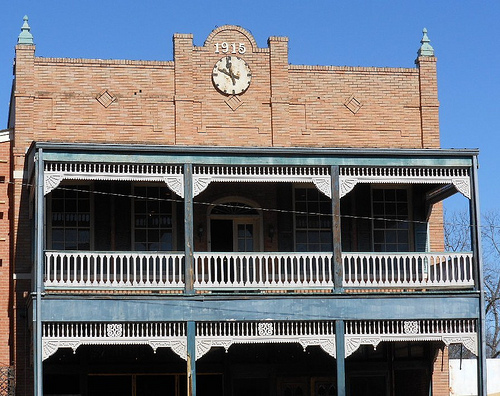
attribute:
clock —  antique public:
[206, 49, 257, 94]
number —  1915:
[214, 36, 260, 56]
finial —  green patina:
[16, 136, 483, 384]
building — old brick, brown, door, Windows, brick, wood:
[11, 14, 484, 389]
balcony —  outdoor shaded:
[15, 132, 481, 393]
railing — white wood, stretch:
[25, 135, 467, 386]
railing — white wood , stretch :
[12, 121, 481, 376]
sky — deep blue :
[71, 11, 445, 33]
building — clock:
[211, 51, 254, 99]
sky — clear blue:
[321, 14, 440, 41]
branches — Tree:
[438, 219, 483, 249]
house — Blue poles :
[24, 154, 484, 393]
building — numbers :
[194, 40, 256, 53]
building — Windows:
[5, 21, 443, 131]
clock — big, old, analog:
[211, 54, 250, 94]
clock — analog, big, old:
[209, 57, 254, 97]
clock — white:
[214, 58, 250, 96]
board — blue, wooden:
[182, 320, 200, 394]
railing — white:
[340, 246, 471, 286]